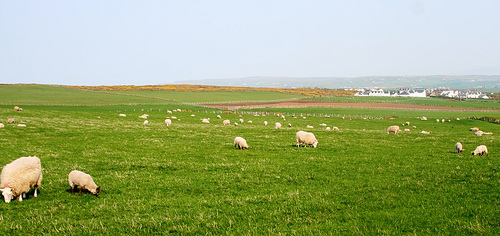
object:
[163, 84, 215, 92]
hills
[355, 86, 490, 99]
dwellings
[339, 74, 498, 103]
town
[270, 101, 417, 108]
land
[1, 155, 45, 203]
sheep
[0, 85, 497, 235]
pasture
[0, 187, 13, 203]
face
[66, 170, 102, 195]
sheep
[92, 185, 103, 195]
face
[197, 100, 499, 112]
dirt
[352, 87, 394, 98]
buildings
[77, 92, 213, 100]
grass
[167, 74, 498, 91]
mountain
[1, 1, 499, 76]
sky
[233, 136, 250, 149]
sheep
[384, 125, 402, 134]
sheep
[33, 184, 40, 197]
leg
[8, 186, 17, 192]
ear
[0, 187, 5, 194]
ear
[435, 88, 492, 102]
houses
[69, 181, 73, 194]
leg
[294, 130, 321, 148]
sheep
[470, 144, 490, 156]
sheep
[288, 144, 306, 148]
shadow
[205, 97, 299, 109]
road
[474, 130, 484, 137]
sheep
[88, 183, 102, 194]
head